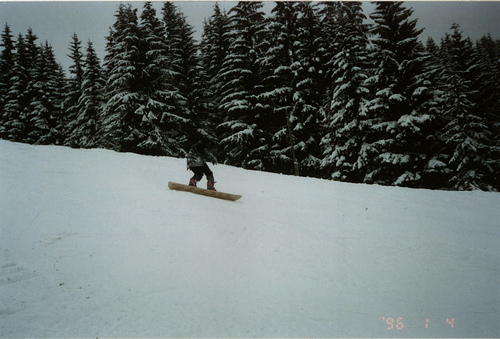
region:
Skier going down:
[158, 125, 248, 206]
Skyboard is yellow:
[158, 178, 244, 203]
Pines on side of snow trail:
[0, 4, 495, 159]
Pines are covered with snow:
[117, 3, 481, 158]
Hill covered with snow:
[1, 127, 496, 333]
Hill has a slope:
[124, 151, 499, 326]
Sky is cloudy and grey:
[5, 0, 493, 60]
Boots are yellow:
[183, 175, 219, 192]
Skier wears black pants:
[178, 132, 220, 197]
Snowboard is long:
[156, 168, 251, 210]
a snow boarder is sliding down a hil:
[168, 124, 243, 206]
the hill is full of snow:
[1, 133, 482, 336]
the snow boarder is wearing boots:
[186, 175, 218, 191]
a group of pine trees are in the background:
[0, 9, 499, 196]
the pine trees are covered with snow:
[1, 4, 496, 193]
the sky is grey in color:
[0, 3, 492, 109]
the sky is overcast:
[4, 4, 496, 117]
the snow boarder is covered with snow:
[178, 131, 222, 191]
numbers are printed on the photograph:
[381, 311, 461, 337]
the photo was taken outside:
[3, 5, 498, 337]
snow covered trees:
[2, 25, 496, 207]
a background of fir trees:
[12, 18, 490, 212]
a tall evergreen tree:
[63, 22, 121, 152]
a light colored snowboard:
[161, 172, 257, 207]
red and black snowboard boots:
[183, 173, 229, 193]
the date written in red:
[372, 310, 471, 335]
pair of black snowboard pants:
[177, 154, 222, 187]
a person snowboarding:
[159, 133, 265, 216]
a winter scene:
[22, 72, 493, 332]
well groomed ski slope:
[23, 120, 493, 322]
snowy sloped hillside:
[0, 137, 499, 335]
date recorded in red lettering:
[381, 315, 455, 331]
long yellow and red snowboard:
[168, 181, 243, 201]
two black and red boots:
[188, 177, 216, 189]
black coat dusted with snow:
[185, 145, 215, 167]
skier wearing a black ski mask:
[196, 138, 207, 152]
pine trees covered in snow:
[0, 0, 499, 189]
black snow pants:
[190, 163, 212, 180]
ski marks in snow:
[2, 230, 133, 337]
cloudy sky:
[0, 0, 499, 85]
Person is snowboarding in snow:
[165, 131, 263, 223]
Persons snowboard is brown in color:
[161, 173, 248, 215]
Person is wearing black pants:
[177, 151, 222, 189]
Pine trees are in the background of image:
[0, 5, 495, 193]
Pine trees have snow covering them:
[8, 0, 493, 195]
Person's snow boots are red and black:
[182, 175, 227, 200]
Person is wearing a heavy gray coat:
[169, 132, 221, 176]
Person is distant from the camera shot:
[143, 126, 258, 224]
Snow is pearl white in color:
[8, 180, 490, 337]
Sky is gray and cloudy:
[0, 0, 492, 66]